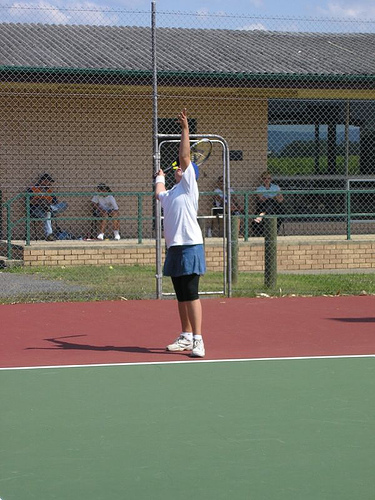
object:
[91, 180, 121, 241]
child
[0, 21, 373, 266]
building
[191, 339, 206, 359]
feet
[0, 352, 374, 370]
line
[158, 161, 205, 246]
t-shirt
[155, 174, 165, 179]
wristband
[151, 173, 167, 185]
sweatband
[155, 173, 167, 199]
arm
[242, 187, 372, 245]
green handrail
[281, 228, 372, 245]
deck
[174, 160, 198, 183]
head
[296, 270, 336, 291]
green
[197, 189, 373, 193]
pole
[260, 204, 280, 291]
pole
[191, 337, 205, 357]
shoe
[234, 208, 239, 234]
leg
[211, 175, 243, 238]
person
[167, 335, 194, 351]
feet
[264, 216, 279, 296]
green pole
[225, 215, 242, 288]
green pole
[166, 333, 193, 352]
tennis shoe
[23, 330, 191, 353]
shadow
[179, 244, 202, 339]
leg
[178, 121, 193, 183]
arm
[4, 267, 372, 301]
grass section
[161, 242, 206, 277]
skirt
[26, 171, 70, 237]
people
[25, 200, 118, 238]
chairs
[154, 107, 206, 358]
person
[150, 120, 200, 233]
gate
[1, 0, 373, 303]
fence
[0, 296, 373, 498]
court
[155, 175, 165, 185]
wrist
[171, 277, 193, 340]
leg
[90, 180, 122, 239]
person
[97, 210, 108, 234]
leg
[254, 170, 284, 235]
person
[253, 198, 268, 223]
leg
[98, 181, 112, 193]
ponytail